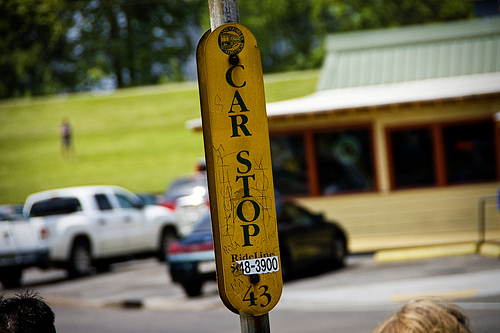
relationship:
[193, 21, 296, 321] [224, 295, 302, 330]
sign on pole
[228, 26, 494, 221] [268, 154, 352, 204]
restaurant has customers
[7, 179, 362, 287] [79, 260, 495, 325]
cars in parking lot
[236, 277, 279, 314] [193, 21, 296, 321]
number on sign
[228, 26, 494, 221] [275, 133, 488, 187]
restaurant has windows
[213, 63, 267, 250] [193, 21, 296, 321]
car stop in front of sign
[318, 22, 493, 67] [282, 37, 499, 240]
roof on top of building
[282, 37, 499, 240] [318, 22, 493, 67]
building has roof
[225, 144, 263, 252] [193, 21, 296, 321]
stop on sign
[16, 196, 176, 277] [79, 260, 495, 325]
truck parked in parking lot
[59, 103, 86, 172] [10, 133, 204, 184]
person standing in grass